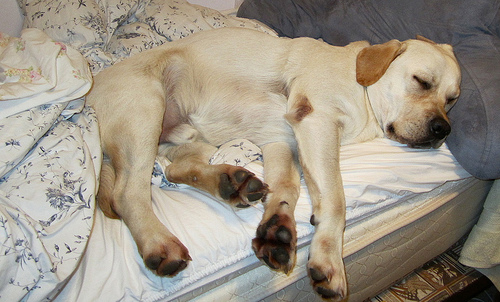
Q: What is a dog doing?
A: Sleeping.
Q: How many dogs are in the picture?
A: One.